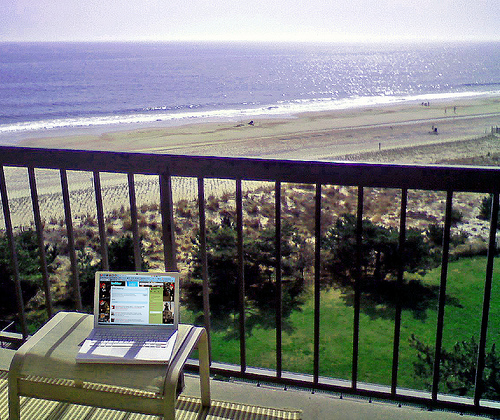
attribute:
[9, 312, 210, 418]
table — small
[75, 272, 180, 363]
laptop — white, open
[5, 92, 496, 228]
sand — tan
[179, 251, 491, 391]
grass — green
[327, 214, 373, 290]
tree — green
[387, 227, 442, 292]
tree — green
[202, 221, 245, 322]
tree — green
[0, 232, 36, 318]
tree — green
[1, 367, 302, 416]
rug — beige, striped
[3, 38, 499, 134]
water — blue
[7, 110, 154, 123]
wave — white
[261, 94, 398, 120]
wave — white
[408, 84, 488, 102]
wave — white